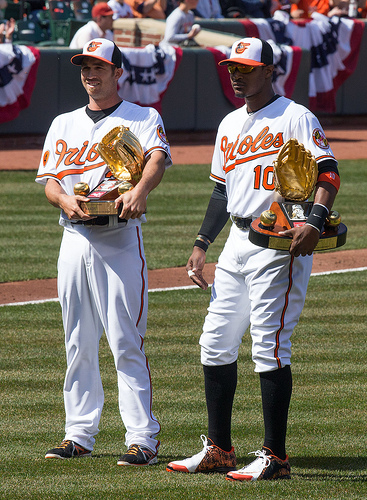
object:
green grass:
[81, 452, 107, 468]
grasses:
[1, 467, 38, 497]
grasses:
[0, 217, 25, 282]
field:
[0, 116, 364, 498]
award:
[271, 134, 315, 204]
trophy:
[246, 137, 346, 257]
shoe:
[167, 444, 239, 473]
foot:
[166, 436, 235, 474]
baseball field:
[4, 126, 365, 495]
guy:
[172, 39, 339, 475]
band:
[186, 236, 212, 253]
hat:
[214, 35, 274, 70]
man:
[181, 33, 341, 482]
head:
[216, 37, 280, 107]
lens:
[236, 62, 252, 72]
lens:
[226, 63, 237, 72]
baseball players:
[33, 33, 170, 467]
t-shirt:
[207, 94, 321, 240]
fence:
[1, 18, 365, 162]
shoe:
[222, 444, 296, 484]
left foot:
[236, 408, 294, 488]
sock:
[255, 365, 295, 454]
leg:
[246, 279, 297, 462]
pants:
[60, 226, 149, 442]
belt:
[68, 213, 128, 225]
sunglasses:
[225, 62, 254, 74]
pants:
[131, 226, 157, 384]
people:
[2, 5, 76, 47]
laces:
[122, 444, 138, 456]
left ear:
[112, 65, 127, 83]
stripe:
[272, 254, 296, 369]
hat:
[68, 34, 122, 69]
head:
[78, 62, 122, 98]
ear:
[264, 62, 274, 79]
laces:
[53, 436, 75, 450]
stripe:
[139, 374, 166, 460]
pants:
[196, 218, 312, 374]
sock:
[200, 359, 239, 453]